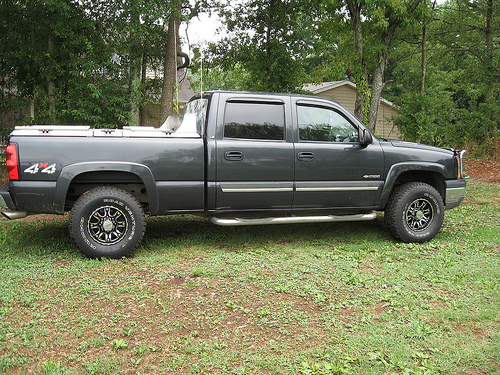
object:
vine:
[351, 58, 372, 126]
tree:
[144, 0, 196, 128]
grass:
[0, 180, 500, 375]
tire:
[384, 181, 445, 244]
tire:
[67, 186, 148, 261]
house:
[0, 20, 195, 128]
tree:
[250, 0, 428, 144]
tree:
[0, 1, 145, 145]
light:
[5, 145, 19, 181]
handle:
[297, 151, 314, 162]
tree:
[339, 0, 419, 135]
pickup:
[0, 90, 470, 260]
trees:
[0, 0, 500, 160]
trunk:
[157, 0, 180, 128]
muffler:
[0, 210, 27, 220]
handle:
[224, 150, 244, 161]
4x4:
[23, 163, 57, 175]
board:
[210, 209, 378, 226]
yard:
[0, 247, 500, 375]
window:
[224, 101, 286, 141]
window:
[297, 104, 360, 143]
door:
[215, 93, 294, 213]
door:
[290, 98, 385, 214]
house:
[295, 80, 405, 141]